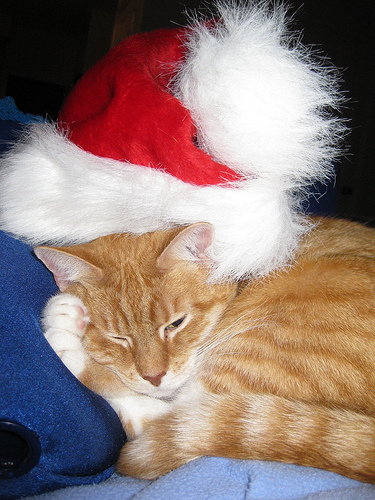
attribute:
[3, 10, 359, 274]
hat — red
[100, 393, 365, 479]
tail — striped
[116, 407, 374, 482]
tail — long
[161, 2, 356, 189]
cotton — white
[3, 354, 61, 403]
pillow — blue 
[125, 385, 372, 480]
tail — cat's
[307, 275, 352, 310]
fur — brown 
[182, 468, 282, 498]
blanket — blue 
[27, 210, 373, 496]
cat — brown, white, orange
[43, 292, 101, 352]
paw — white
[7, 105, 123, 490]
pillow — blue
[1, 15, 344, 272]
cloth — white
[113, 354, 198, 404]
mouth — white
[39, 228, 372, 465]
cat — lying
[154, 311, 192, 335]
eye — yellow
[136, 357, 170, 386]
nose — red